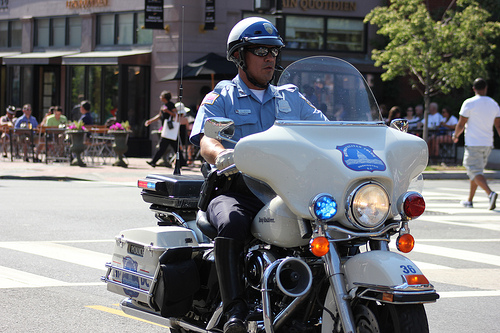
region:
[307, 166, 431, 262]
the lights on the cops motorcycle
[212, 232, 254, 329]
the boot on the mans leg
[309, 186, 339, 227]
the blue light is on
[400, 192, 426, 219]
the red light on the bike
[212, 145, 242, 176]
the white glove holding the handle bar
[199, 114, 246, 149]
the sideview mirror on the bike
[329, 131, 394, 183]
the police shield on the hood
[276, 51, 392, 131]
the windshield on the bike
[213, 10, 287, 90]
the helmet on the cops head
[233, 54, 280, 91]
the strap under the chin of the officer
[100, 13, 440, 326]
police officer on motorcycle on city road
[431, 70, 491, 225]
pedestrian crossing street on white striped lines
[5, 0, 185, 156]
building with dark facade and dark windows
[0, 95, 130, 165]
people seated at outdoor cafe decorated with flowers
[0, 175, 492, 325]
flat gray paved street with yellow and white lines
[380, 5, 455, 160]
small tree in front of outdoor diners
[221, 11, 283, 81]
officer wearing helmet and sunglasses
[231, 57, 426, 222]
small windshield over curved white panel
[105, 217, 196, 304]
white container behind bars on side of motorcycle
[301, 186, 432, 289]
broken orange headlight on front of motorcycle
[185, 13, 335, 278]
police officer on a motorcycle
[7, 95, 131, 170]
people sitting at tables on the sidewalk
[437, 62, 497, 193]
person crossing the street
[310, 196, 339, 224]
blue light is shining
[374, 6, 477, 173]
tree is growing on the sidewalk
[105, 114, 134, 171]
tall planter with flowers blooming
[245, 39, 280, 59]
man is wearing sunglasses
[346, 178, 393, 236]
headlight is on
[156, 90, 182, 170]
person is carrying a large bag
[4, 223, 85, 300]
white lines on the pavement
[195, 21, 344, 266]
officer is wearing uniform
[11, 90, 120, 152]
people sitting at the restaurant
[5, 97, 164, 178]
people sitting at the restaurant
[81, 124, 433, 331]
the police bike is white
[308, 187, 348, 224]
the blue light is on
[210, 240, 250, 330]
the boots are black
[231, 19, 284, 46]
the helmet is blue and white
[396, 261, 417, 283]
number 36 is on the bumper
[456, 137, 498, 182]
the shorts are brown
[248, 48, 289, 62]
the gogles are on the face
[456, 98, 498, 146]
the shirt is white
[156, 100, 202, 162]
the man is dressed in black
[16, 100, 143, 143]
the people are sitted